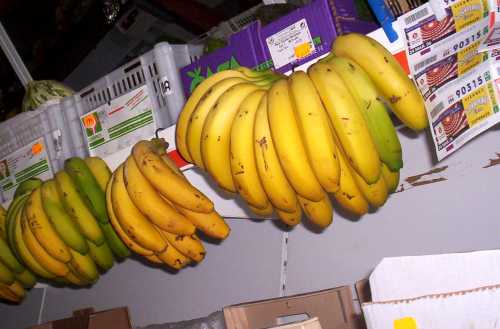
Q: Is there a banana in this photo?
A: Yes, there is a banana.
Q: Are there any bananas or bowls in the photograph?
A: Yes, there is a banana.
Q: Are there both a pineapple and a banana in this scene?
A: No, there is a banana but no pineapples.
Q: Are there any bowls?
A: No, there are no bowls.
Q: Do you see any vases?
A: No, there are no vases.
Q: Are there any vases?
A: No, there are no vases.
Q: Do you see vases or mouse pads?
A: No, there are no vases or mouse pads.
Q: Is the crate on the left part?
A: Yes, the crate is on the left of the image.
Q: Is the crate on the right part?
A: No, the crate is on the left of the image.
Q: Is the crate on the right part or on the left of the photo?
A: The crate is on the left of the image.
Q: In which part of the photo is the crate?
A: The crate is on the left of the image.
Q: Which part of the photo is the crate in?
A: The crate is on the left of the image.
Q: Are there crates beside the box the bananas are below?
A: Yes, there is a crate beside the box.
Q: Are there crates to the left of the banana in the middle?
A: Yes, there is a crate to the left of the banana.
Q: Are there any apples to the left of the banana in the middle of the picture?
A: No, there is a crate to the left of the banana.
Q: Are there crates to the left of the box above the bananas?
A: Yes, there is a crate to the left of the box.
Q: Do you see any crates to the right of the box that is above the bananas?
A: No, the crate is to the left of the box.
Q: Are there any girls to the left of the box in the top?
A: No, there is a crate to the left of the box.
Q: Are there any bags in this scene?
A: No, there are no bags.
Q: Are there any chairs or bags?
A: No, there are no bags or chairs.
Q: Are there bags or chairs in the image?
A: No, there are no bags or chairs.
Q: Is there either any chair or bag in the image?
A: No, there are no bags or chairs.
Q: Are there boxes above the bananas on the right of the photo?
A: Yes, there is a box above the bananas.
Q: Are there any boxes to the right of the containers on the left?
A: Yes, there is a box to the right of the containers.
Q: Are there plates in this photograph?
A: No, there are no plates.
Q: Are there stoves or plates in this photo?
A: No, there are no plates or stoves.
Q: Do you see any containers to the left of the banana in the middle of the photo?
A: Yes, there are containers to the left of the banana.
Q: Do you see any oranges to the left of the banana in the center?
A: No, there are containers to the left of the banana.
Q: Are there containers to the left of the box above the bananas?
A: Yes, there are containers to the left of the box.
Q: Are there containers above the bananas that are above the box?
A: Yes, there are containers above the bananas.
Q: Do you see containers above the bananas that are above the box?
A: Yes, there are containers above the bananas.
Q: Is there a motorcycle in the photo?
A: No, there are no motorcycles.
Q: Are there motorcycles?
A: No, there are no motorcycles.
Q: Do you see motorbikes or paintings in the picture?
A: No, there are no motorbikes or paintings.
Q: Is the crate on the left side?
A: Yes, the crate is on the left of the image.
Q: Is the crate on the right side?
A: No, the crate is on the left of the image.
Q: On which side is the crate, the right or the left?
A: The crate is on the left of the image.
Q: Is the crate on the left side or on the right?
A: The crate is on the left of the image.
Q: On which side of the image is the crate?
A: The crate is on the left of the image.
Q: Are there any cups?
A: No, there are no cups.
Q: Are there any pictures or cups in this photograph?
A: No, there are no cups or pictures.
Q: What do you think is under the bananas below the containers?
A: The box is under the bananas.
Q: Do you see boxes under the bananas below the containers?
A: Yes, there is a box under the bananas.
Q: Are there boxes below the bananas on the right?
A: Yes, there is a box below the bananas.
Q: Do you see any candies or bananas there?
A: Yes, there is a banana.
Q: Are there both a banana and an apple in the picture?
A: No, there is a banana but no apples.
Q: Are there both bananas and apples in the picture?
A: No, there is a banana but no apples.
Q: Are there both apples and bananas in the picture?
A: No, there is a banana but no apples.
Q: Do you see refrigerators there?
A: No, there are no refrigerators.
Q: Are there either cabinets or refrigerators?
A: No, there are no refrigerators or cabinets.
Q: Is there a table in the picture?
A: No, there are no tables.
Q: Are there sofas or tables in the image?
A: No, there are no tables or sofas.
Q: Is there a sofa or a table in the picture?
A: No, there are no tables or sofas.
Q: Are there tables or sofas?
A: No, there are no tables or sofas.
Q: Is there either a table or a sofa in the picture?
A: No, there are no tables or sofas.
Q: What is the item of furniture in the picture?
A: The piece of furniture is a shelf.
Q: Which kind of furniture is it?
A: The piece of furniture is a shelf.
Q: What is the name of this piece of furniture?
A: This is a shelf.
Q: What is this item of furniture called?
A: This is a shelf.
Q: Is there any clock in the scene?
A: No, there are no clocks.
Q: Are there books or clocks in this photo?
A: No, there are no clocks or books.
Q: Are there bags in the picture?
A: No, there are no bags.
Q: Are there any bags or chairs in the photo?
A: No, there are no bags or chairs.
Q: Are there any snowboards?
A: No, there are no snowboards.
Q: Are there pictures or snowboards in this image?
A: No, there are no snowboards or pictures.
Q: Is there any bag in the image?
A: No, there are no bags.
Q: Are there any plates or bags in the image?
A: No, there are no bags or plates.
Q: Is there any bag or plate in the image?
A: No, there are no bags or plates.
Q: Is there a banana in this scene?
A: Yes, there is a banana.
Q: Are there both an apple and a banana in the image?
A: No, there is a banana but no apples.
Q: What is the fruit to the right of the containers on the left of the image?
A: The fruit is a banana.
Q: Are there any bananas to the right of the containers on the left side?
A: Yes, there is a banana to the right of the containers.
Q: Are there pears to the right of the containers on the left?
A: No, there is a banana to the right of the containers.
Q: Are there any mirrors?
A: No, there are no mirrors.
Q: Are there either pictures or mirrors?
A: No, there are no mirrors or pictures.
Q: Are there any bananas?
A: Yes, there are bananas.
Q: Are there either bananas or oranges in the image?
A: Yes, there are bananas.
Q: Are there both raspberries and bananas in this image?
A: No, there are bananas but no raspberries.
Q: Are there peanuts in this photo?
A: No, there are no peanuts.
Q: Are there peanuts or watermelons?
A: No, there are no peanuts or watermelons.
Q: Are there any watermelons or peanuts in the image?
A: No, there are no peanuts or watermelons.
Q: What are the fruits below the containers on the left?
A: The fruits are bananas.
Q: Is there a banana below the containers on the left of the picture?
A: Yes, there are bananas below the containers.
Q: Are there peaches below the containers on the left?
A: No, there are bananas below the containers.